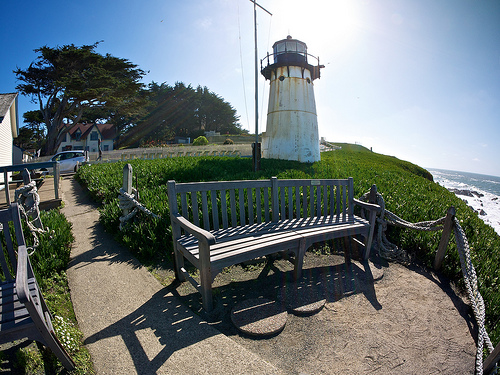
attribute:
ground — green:
[74, 141, 499, 310]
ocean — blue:
[421, 167, 499, 238]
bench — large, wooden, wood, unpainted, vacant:
[165, 176, 381, 311]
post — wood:
[433, 204, 460, 273]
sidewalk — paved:
[59, 173, 284, 375]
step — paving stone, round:
[230, 295, 288, 338]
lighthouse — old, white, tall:
[260, 32, 325, 167]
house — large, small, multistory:
[56, 122, 118, 152]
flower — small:
[56, 312, 66, 323]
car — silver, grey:
[33, 149, 91, 173]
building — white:
[0, 91, 20, 189]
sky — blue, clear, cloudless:
[1, 1, 499, 177]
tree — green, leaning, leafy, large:
[16, 37, 149, 160]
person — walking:
[96, 134, 104, 160]